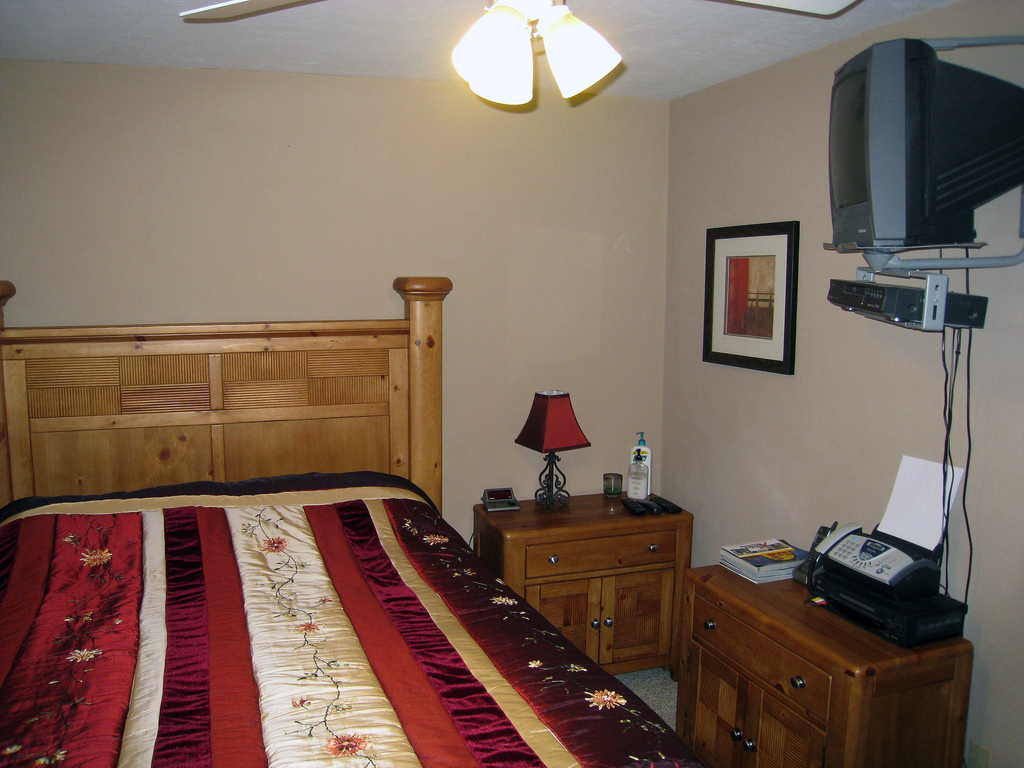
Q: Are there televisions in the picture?
A: Yes, there is a television.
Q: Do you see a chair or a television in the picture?
A: Yes, there is a television.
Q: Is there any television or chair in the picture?
A: Yes, there is a television.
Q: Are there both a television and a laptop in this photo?
A: No, there is a television but no laptops.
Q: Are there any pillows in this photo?
A: No, there are no pillows.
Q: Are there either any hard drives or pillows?
A: No, there are no pillows or hard drives.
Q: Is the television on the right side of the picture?
A: Yes, the television is on the right of the image.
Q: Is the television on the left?
A: No, the television is on the right of the image.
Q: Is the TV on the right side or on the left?
A: The TV is on the right of the image.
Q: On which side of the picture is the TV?
A: The TV is on the right of the image.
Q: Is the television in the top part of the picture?
A: Yes, the television is in the top of the image.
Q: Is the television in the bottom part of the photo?
A: No, the television is in the top of the image.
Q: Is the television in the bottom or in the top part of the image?
A: The television is in the top of the image.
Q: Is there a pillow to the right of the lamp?
A: No, there are bottles to the right of the lamp.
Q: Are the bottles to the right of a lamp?
A: Yes, the bottles are to the right of a lamp.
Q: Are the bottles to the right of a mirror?
A: No, the bottles are to the right of a lamp.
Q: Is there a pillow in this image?
A: No, there are no pillows.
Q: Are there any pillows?
A: No, there are no pillows.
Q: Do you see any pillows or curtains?
A: No, there are no pillows or curtains.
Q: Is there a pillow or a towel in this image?
A: No, there are no pillows or towels.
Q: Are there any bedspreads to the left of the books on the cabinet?
A: Yes, there is a bedspread to the left of the books.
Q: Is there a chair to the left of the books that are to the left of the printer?
A: No, there is a bedspread to the left of the books.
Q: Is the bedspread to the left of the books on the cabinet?
A: Yes, the bedspread is to the left of the books.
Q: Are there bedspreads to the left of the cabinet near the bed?
A: Yes, there is a bedspread to the left of the cabinet.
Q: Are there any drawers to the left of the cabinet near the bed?
A: No, there is a bedspread to the left of the cabinet.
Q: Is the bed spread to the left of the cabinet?
A: Yes, the bed spread is to the left of the cabinet.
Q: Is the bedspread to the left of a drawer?
A: No, the bedspread is to the left of the cabinet.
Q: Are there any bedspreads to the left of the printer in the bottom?
A: Yes, there is a bedspread to the left of the printer.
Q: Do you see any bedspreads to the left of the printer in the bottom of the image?
A: Yes, there is a bedspread to the left of the printer.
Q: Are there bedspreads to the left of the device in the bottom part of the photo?
A: Yes, there is a bedspread to the left of the printer.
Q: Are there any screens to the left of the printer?
A: No, there is a bedspread to the left of the printer.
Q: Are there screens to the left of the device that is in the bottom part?
A: No, there is a bedspread to the left of the printer.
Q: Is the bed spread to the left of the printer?
A: Yes, the bed spread is to the left of the printer.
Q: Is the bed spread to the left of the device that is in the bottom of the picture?
A: Yes, the bed spread is to the left of the printer.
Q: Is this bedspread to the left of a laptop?
A: No, the bedspread is to the left of the printer.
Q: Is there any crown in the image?
A: No, there are no crowns.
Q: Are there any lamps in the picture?
A: Yes, there is a lamp.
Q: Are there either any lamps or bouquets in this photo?
A: Yes, there is a lamp.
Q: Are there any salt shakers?
A: No, there are no salt shakers.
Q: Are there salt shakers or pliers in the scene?
A: No, there are no salt shakers or pliers.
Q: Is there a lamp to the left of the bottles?
A: Yes, there is a lamp to the left of the bottles.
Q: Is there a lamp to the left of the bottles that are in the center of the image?
A: Yes, there is a lamp to the left of the bottles.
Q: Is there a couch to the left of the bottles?
A: No, there is a lamp to the left of the bottles.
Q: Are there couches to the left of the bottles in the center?
A: No, there is a lamp to the left of the bottles.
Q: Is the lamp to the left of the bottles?
A: Yes, the lamp is to the left of the bottles.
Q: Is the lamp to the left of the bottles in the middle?
A: Yes, the lamp is to the left of the bottles.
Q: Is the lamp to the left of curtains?
A: No, the lamp is to the left of the bottles.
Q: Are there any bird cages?
A: No, there are no bird cages.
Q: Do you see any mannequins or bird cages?
A: No, there are no bird cages or mannequins.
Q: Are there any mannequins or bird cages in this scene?
A: No, there are no bird cages or mannequins.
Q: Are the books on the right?
A: Yes, the books are on the right of the image.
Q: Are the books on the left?
A: No, the books are on the right of the image.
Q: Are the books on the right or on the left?
A: The books are on the right of the image.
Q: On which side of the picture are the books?
A: The books are on the right of the image.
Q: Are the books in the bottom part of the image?
A: Yes, the books are in the bottom of the image.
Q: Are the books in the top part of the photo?
A: No, the books are in the bottom of the image.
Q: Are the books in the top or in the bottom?
A: The books are in the bottom of the image.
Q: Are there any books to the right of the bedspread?
A: Yes, there are books to the right of the bedspread.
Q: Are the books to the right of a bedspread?
A: Yes, the books are to the right of a bedspread.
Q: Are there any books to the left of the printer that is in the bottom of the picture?
A: Yes, there are books to the left of the printer.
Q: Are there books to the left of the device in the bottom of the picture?
A: Yes, there are books to the left of the printer.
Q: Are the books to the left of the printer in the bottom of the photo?
A: Yes, the books are to the left of the printer.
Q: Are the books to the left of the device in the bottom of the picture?
A: Yes, the books are to the left of the printer.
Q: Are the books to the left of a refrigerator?
A: No, the books are to the left of the printer.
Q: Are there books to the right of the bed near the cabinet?
A: Yes, there are books to the right of the bed.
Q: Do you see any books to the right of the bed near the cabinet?
A: Yes, there are books to the right of the bed.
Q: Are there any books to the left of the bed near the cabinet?
A: No, the books are to the right of the bed.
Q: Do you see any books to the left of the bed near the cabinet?
A: No, the books are to the right of the bed.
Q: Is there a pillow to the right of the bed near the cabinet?
A: No, there are books to the right of the bed.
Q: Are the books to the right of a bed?
A: Yes, the books are to the right of a bed.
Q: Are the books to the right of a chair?
A: No, the books are to the right of a bed.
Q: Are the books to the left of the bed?
A: No, the books are to the right of the bed.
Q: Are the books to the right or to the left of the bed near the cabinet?
A: The books are to the right of the bed.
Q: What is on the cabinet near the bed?
A: The books are on the cabinet.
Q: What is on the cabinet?
A: The books are on the cabinet.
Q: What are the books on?
A: The books are on the cabinet.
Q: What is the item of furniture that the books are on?
A: The piece of furniture is a cabinet.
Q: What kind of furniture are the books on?
A: The books are on the cabinet.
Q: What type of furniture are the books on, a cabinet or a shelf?
A: The books are on a cabinet.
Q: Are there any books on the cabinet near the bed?
A: Yes, there are books on the cabinet.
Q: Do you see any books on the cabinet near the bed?
A: Yes, there are books on the cabinet.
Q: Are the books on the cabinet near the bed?
A: Yes, the books are on the cabinet.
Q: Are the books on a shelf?
A: No, the books are on the cabinet.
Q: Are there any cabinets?
A: Yes, there is a cabinet.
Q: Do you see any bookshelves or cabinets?
A: Yes, there is a cabinet.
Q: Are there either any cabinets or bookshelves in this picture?
A: Yes, there is a cabinet.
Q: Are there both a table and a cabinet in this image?
A: Yes, there are both a cabinet and a table.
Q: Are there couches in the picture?
A: No, there are no couches.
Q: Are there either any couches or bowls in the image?
A: No, there are no couches or bowls.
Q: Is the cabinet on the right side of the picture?
A: Yes, the cabinet is on the right of the image.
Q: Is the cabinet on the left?
A: No, the cabinet is on the right of the image.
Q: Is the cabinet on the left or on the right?
A: The cabinet is on the right of the image.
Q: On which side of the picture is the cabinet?
A: The cabinet is on the right of the image.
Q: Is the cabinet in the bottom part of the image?
A: Yes, the cabinet is in the bottom of the image.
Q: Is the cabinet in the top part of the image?
A: No, the cabinet is in the bottom of the image.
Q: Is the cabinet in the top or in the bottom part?
A: The cabinet is in the bottom of the image.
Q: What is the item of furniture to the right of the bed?
A: The piece of furniture is a cabinet.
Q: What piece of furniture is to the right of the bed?
A: The piece of furniture is a cabinet.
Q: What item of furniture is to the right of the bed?
A: The piece of furniture is a cabinet.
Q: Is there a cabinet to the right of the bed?
A: Yes, there is a cabinet to the right of the bed.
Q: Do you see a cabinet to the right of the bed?
A: Yes, there is a cabinet to the right of the bed.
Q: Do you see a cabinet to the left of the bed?
A: No, the cabinet is to the right of the bed.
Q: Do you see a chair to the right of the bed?
A: No, there is a cabinet to the right of the bed.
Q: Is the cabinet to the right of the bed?
A: Yes, the cabinet is to the right of the bed.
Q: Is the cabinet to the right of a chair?
A: No, the cabinet is to the right of the bed.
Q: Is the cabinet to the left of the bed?
A: No, the cabinet is to the right of the bed.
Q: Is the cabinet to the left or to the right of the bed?
A: The cabinet is to the right of the bed.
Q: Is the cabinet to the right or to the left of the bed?
A: The cabinet is to the right of the bed.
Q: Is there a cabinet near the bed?
A: Yes, there is a cabinet near the bed.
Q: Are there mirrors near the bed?
A: No, there is a cabinet near the bed.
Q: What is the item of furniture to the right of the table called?
A: The piece of furniture is a cabinet.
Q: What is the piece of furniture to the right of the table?
A: The piece of furniture is a cabinet.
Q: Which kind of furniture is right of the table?
A: The piece of furniture is a cabinet.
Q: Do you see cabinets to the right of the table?
A: Yes, there is a cabinet to the right of the table.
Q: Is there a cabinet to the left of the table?
A: No, the cabinet is to the right of the table.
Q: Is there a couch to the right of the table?
A: No, there is a cabinet to the right of the table.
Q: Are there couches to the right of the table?
A: No, there is a cabinet to the right of the table.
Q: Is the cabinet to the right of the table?
A: Yes, the cabinet is to the right of the table.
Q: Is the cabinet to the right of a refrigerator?
A: No, the cabinet is to the right of the table.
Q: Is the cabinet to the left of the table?
A: No, the cabinet is to the right of the table.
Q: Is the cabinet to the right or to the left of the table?
A: The cabinet is to the right of the table.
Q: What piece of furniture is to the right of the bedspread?
A: The piece of furniture is a cabinet.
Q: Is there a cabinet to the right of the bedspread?
A: Yes, there is a cabinet to the right of the bedspread.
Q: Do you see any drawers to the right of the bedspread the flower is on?
A: No, there is a cabinet to the right of the bedspread.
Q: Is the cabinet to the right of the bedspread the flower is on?
A: Yes, the cabinet is to the right of the bedspread.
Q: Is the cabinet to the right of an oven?
A: No, the cabinet is to the right of the bedspread.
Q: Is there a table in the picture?
A: Yes, there is a table.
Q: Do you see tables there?
A: Yes, there is a table.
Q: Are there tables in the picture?
A: Yes, there is a table.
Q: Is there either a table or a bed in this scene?
A: Yes, there is a table.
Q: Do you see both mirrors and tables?
A: No, there is a table but no mirrors.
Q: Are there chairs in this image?
A: No, there are no chairs.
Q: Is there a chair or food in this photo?
A: No, there are no chairs or food.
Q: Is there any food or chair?
A: No, there are no chairs or food.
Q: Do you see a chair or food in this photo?
A: No, there are no chairs or food.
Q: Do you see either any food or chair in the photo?
A: No, there are no chairs or food.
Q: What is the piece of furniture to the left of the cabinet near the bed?
A: The piece of furniture is a table.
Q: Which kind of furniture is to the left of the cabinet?
A: The piece of furniture is a table.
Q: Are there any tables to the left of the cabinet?
A: Yes, there is a table to the left of the cabinet.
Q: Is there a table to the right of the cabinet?
A: No, the table is to the left of the cabinet.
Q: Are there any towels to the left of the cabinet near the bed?
A: No, there is a table to the left of the cabinet.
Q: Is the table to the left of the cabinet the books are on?
A: Yes, the table is to the left of the cabinet.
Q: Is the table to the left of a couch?
A: No, the table is to the left of the cabinet.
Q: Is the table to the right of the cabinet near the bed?
A: No, the table is to the left of the cabinet.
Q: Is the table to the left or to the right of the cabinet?
A: The table is to the left of the cabinet.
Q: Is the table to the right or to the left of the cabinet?
A: The table is to the left of the cabinet.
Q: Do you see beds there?
A: Yes, there is a bed.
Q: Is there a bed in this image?
A: Yes, there is a bed.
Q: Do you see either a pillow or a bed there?
A: Yes, there is a bed.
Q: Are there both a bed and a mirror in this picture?
A: No, there is a bed but no mirrors.